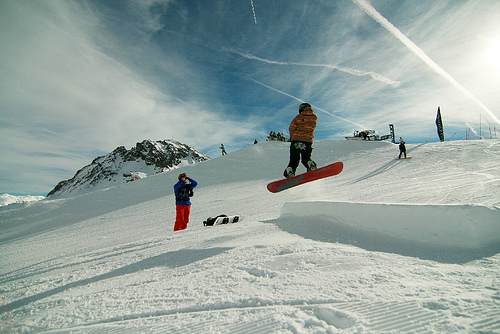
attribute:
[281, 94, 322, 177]
person — jumping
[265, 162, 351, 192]
snowboard — red, long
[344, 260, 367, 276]
snow — black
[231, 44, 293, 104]
lines — white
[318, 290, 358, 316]
lines — straight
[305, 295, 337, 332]
print — large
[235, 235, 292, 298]
snow — white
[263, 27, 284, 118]
streaks — white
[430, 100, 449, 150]
flag — large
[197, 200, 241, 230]
bag — black, white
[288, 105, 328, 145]
jacket — brown, red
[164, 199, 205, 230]
pants — red